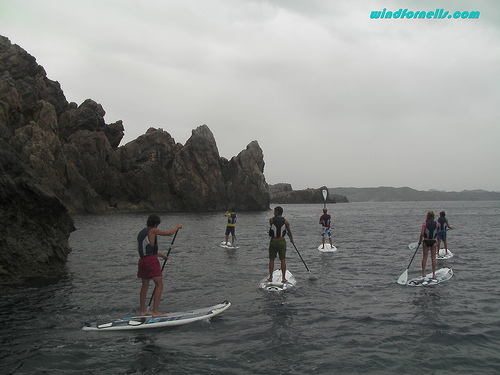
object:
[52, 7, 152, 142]
cloud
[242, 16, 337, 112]
part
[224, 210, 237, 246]
man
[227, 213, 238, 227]
yellow shirt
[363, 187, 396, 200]
wall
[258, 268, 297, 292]
paddleboard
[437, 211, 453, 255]
people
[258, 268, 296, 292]
boards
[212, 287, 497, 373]
wave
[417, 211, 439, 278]
person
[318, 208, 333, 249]
man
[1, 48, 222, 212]
cliff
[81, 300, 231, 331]
board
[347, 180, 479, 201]
mountains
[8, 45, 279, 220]
rocky terrain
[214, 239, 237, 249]
paddleboard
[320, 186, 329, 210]
paddle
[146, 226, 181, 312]
paddle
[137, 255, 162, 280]
red shorts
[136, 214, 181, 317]
man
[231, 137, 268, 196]
cliff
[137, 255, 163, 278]
pink shorts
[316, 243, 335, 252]
paddleboard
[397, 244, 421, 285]
paddle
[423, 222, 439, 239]
shirt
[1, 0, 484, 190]
sky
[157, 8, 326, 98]
cloud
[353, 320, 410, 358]
water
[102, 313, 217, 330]
edge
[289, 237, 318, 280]
oar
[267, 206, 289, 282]
man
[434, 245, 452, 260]
paddleboard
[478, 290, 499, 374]
water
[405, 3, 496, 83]
cloud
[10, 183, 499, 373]
ocean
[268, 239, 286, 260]
swim trunks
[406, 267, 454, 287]
paddleboard